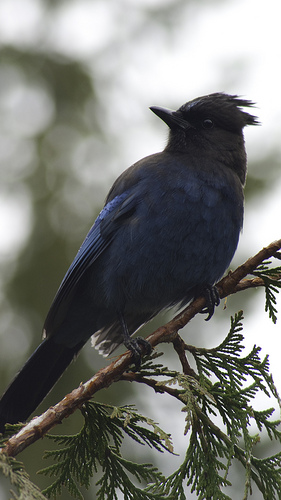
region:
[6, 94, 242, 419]
that is a bird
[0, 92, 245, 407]
that is a blue bird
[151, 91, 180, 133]
the beak of the bird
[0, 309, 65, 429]
the tail of the birds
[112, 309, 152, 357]
that is the leg of the bird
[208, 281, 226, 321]
that is the leg of the bird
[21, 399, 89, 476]
a branch of a tree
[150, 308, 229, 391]
the branch of a tree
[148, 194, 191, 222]
feathers of the bird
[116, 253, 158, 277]
feathers of the bird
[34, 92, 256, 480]
Black and blue bird on limb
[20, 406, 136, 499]
Green leaves on a tree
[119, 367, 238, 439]
Green leaves on a tree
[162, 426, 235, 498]
Green leaves on a tree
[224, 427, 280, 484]
Green leaves on a tree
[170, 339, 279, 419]
Green leaves on a tree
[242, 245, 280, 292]
Green leaves on a tree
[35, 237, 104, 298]
Black and blue feathers on bird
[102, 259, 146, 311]
Black and blue feathers on bird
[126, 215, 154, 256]
Black and blue feathers on bird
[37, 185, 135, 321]
blue and black feathers on a bird's wing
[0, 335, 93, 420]
tail feathers of a bird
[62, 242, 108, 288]
layers of wing feathers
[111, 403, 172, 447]
browning needles on an evergreen tree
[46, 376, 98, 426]
brown bark on a branch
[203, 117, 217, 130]
the eye of a bird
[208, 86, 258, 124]
spiky feathers on a bird's head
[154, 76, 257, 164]
the head of a bird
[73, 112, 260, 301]
a bird with blue and black feathers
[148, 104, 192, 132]
the beak of a bird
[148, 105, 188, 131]
beak of a bird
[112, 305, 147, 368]
claw of a bird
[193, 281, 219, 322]
claw of a bird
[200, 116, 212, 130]
eye of a bird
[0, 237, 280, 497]
stem of a tree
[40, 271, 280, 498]
thin green leaves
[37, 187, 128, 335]
wing of a blue bird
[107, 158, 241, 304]
body of a bird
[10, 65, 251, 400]
a bird with blue and black feathers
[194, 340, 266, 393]
needles of an evergreen tree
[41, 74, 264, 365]
a bird perched on a branch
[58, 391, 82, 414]
bark on a branch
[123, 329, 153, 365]
the claw of a bird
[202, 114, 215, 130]
the left eye of a bird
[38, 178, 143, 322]
the wing of a bird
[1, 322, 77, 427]
a bird's tail feathers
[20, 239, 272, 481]
a branch with growth off it